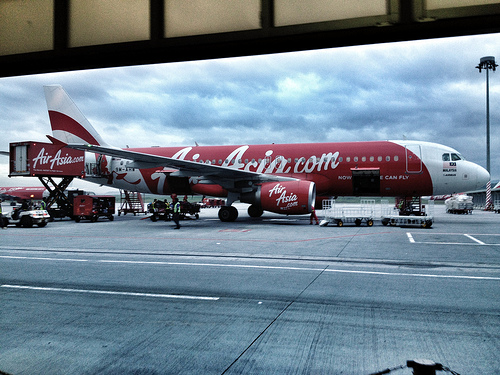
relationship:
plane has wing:
[44, 97, 497, 215] [123, 135, 309, 208]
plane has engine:
[44, 97, 497, 215] [269, 176, 324, 220]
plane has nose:
[44, 97, 497, 215] [455, 134, 499, 201]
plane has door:
[44, 97, 497, 215] [397, 137, 435, 174]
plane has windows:
[44, 97, 497, 215] [253, 138, 415, 184]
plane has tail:
[44, 97, 497, 215] [36, 80, 114, 175]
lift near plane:
[16, 132, 82, 224] [44, 97, 497, 215]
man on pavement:
[157, 181, 190, 219] [295, 281, 477, 370]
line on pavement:
[21, 287, 220, 313] [295, 281, 477, 370]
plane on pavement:
[44, 97, 497, 215] [295, 281, 477, 370]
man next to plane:
[157, 181, 190, 219] [44, 97, 497, 215]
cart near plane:
[34, 189, 134, 230] [44, 97, 497, 215]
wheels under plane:
[211, 196, 276, 234] [44, 97, 497, 215]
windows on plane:
[253, 138, 415, 184] [44, 97, 497, 215]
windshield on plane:
[451, 155, 459, 170] [44, 97, 497, 215]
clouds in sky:
[298, 86, 403, 138] [127, 27, 489, 132]